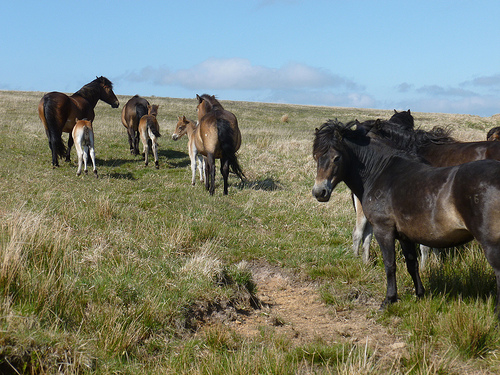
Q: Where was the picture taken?
A: On a field.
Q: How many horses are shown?
A: Nine horses.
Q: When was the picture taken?
A: During the daytime.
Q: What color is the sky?
A: Blue.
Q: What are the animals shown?
A: Horses.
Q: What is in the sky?
A: Clouds.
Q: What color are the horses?
A: Brown, and black.